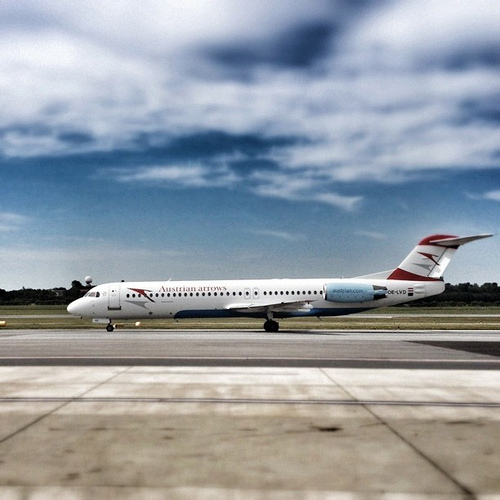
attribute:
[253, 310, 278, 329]
wheel — gear, back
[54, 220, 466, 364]
jet — white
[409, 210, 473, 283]
tail — red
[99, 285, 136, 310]
door — closed, here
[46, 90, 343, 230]
sky — blue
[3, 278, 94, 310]
trees — beyond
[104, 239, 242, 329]
airplane — large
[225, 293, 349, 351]
wing — landing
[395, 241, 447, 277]
arrows — australian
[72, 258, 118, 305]
tower — distant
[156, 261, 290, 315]
windows — lined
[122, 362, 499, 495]
cement — squared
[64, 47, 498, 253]
skies — blue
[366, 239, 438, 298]
airline — named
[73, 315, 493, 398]
runway — edged, here, sectioned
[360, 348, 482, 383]
road — sectioned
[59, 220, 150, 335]
front — here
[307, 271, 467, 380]
back — here